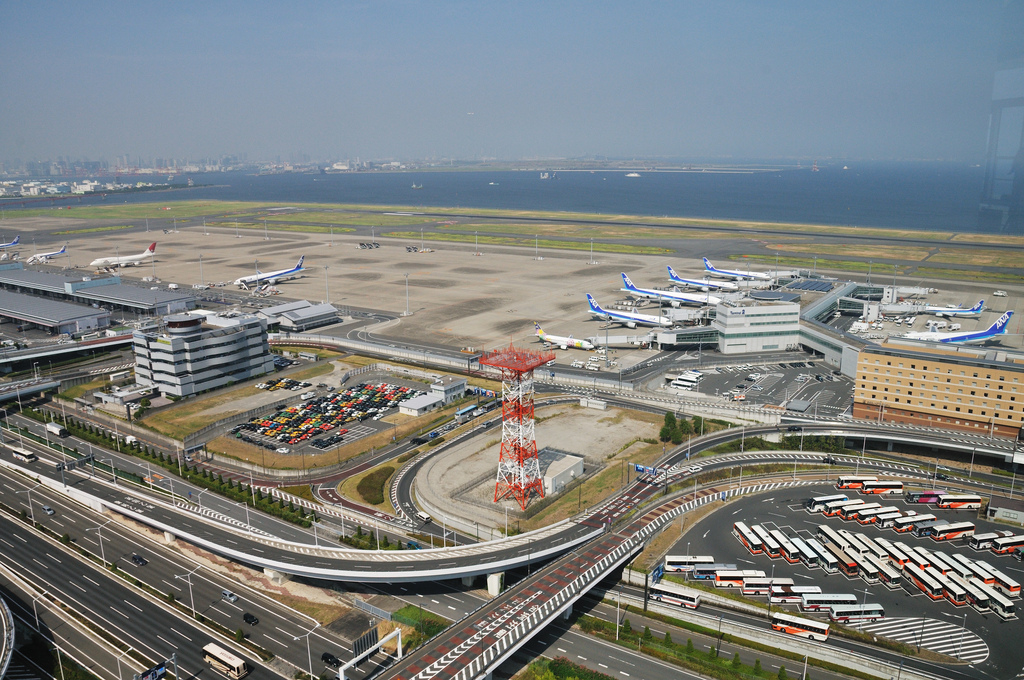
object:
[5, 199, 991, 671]
airport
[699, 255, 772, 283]
plane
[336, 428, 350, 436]
car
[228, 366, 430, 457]
parking lot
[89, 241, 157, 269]
airplane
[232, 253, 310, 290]
airplane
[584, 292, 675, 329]
airplane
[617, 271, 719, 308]
airplane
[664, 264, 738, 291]
airplane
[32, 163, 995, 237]
water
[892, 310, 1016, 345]
plane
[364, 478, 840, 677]
street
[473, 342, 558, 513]
tower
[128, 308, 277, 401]
building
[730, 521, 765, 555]
bus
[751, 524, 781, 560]
bus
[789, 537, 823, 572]
bus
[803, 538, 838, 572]
bus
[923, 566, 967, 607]
bus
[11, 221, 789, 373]
tarmac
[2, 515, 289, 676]
road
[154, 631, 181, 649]
line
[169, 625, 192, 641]
line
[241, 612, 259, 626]
car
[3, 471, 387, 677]
highway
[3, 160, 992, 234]
water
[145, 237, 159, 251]
tail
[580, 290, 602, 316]
tail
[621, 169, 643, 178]
boat